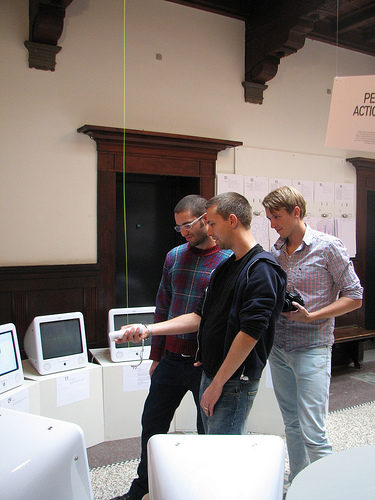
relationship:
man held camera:
[244, 175, 347, 424] [281, 285, 339, 322]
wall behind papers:
[1, 0, 375, 267] [336, 181, 353, 208]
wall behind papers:
[1, 0, 375, 267] [313, 178, 337, 209]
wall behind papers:
[1, 0, 375, 267] [244, 174, 268, 203]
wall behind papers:
[1, 0, 375, 267] [215, 174, 243, 194]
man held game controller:
[124, 192, 282, 432] [108, 323, 144, 342]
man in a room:
[261, 186, 363, 486] [1, 1, 374, 498]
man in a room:
[124, 192, 282, 432] [1, 1, 374, 498]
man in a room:
[109, 194, 235, 500] [1, 1, 374, 498]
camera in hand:
[279, 284, 305, 315] [275, 299, 312, 324]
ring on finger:
[204, 406, 209, 410] [203, 401, 208, 414]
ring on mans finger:
[203, 405, 209, 411] [203, 403, 210, 416]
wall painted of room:
[1, 0, 373, 265] [1, 1, 374, 498]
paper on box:
[56, 372, 91, 407] [23, 357, 106, 448]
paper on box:
[58, 369, 91, 403] [102, 361, 172, 437]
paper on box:
[122, 361, 153, 390] [246, 355, 285, 436]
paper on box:
[263, 363, 273, 386] [41, 375, 102, 443]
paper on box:
[5, 386, 27, 414] [2, 382, 43, 418]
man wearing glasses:
[109, 194, 235, 500] [170, 209, 209, 234]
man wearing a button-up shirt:
[261, 186, 363, 486] [267, 223, 363, 352]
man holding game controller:
[107, 192, 287, 357] [106, 323, 149, 344]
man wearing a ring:
[113, 192, 287, 435] [204, 406, 209, 410]